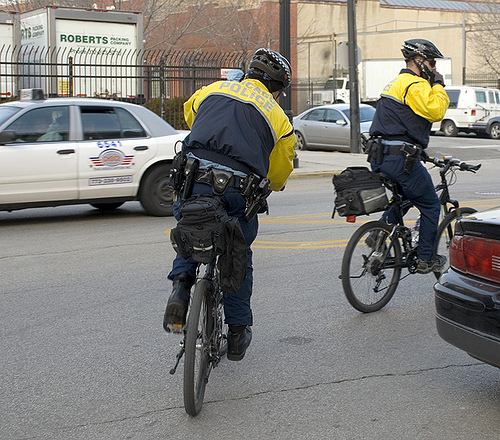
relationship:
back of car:
[427, 220, 498, 372] [432, 196, 498, 374]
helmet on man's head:
[400, 37, 445, 64] [245, 45, 295, 95]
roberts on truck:
[61, 32, 109, 44] [16, 11, 143, 96]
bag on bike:
[171, 196, 229, 262] [321, 151, 443, 310]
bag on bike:
[331, 161, 388, 214] [160, 247, 254, 420]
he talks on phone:
[396, 32, 453, 200] [414, 60, 436, 82]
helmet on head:
[400, 37, 445, 64] [400, 37, 443, 81]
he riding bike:
[166, 45, 292, 362] [130, 215, 245, 370]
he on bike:
[166, 45, 292, 362] [333, 170, 469, 285]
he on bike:
[361, 38, 453, 275] [333, 170, 469, 285]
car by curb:
[291, 102, 391, 154] [294, 163, 339, 184]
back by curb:
[431, 209, 499, 368] [294, 164, 336, 184]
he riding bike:
[166, 45, 292, 362] [169, 198, 243, 415]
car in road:
[1, 85, 193, 222] [11, 232, 165, 409]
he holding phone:
[361, 38, 453, 275] [405, 49, 446, 90]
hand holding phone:
[402, 57, 470, 101] [405, 49, 446, 90]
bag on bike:
[171, 196, 249, 295] [133, 157, 313, 439]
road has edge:
[287, 322, 381, 416] [285, 177, 356, 188]